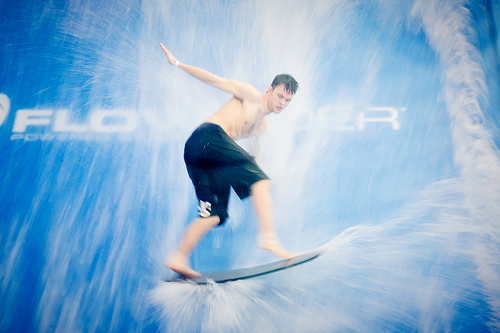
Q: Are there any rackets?
A: No, there are no rackets.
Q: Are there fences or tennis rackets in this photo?
A: No, there are no tennis rackets or fences.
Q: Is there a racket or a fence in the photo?
A: No, there are no rackets or fences.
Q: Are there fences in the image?
A: No, there are no fences.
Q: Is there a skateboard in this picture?
A: No, there are no skateboards.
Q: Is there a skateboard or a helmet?
A: No, there are no skateboards or helmets.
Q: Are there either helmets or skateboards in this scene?
A: No, there are no skateboards or helmets.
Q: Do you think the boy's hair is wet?
A: Yes, the hair is wet.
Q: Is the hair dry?
A: No, the hair is wet.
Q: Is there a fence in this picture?
A: No, there are no fences.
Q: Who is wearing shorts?
A: The boy is wearing shorts.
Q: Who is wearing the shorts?
A: The boy is wearing shorts.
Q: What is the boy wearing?
A: The boy is wearing shorts.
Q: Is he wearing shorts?
A: Yes, the boy is wearing shorts.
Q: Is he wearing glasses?
A: No, the boy is wearing shorts.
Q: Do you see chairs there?
A: No, there are no chairs.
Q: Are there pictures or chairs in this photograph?
A: No, there are no chairs or pictures.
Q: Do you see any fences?
A: No, there are no fences.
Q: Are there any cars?
A: No, there are no cars.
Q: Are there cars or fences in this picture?
A: No, there are no cars or fences.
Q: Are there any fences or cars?
A: No, there are no cars or fences.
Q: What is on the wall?
A: The sign is on the wall.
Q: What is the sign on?
A: The sign is on the wall.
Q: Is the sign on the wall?
A: Yes, the sign is on the wall.